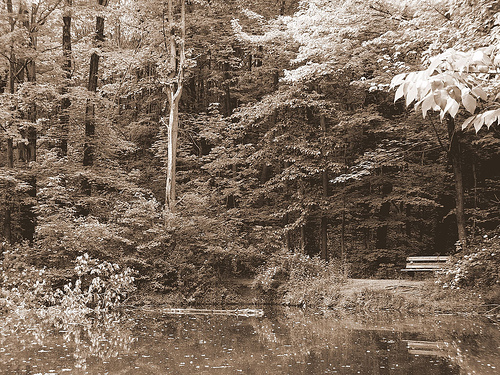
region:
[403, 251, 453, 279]
bench on the ground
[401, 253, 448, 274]
bench in the woods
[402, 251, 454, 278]
bench by the water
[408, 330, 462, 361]
bench reflection in water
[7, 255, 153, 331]
leaves in the water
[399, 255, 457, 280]
wood bench in the woods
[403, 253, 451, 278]
wood bench near the water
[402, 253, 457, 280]
wood bench on the ground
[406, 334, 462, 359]
wood bench reflection in the water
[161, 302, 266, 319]
stick floating on the water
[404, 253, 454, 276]
a bench by a pond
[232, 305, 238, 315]
a bird swimming in the pone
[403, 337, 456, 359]
the reflection of the bench in the water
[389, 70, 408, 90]
the small leaf of the tree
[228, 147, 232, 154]
the small leaf of the tree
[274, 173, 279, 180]
the small leaf of the tree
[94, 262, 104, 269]
the small leaf of the tree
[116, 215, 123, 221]
the small leaf of the tree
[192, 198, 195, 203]
the small leaf of the tree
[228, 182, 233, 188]
the small leaf of the tree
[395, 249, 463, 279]
a bench in the forest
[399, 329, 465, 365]
a reflection of a bench in the water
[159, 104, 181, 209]
a trunk of a tree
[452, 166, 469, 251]
a trunk of a tree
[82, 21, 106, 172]
a trunk of a tree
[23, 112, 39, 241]
a trunk of a tree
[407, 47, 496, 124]
the leaves of a tree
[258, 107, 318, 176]
the leaves of a tree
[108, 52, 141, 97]
the leaves of a tree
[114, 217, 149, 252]
the leaves of a bush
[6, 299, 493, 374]
A pond has bubbles on top.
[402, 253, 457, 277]
A bench has a back.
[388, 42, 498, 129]
Bent over leaves are light in color.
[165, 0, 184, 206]
A tree trunk has a fork.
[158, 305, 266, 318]
A log is in water.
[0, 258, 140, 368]
A bush is in front of water.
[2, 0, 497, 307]
Trees have leaves on the branches.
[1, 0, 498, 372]
A bench is by a pond near thick woods.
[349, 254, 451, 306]
Open area in front of a bench.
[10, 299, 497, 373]
a secluded pond in the woods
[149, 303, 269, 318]
a fallen tree in the water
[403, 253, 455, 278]
a wood slatted park bench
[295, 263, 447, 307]
a cleared are to enjoy the view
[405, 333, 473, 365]
reflection of the bench in the still water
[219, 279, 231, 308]
a person stands by the water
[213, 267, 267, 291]
a peek at the path passing a cleared area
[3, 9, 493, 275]
the trees are mostly slender and young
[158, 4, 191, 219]
tree without it's bark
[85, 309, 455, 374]
leaves are scattered over the water